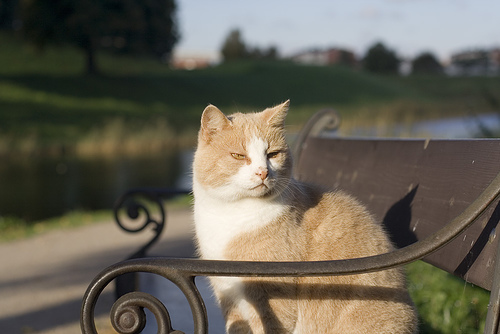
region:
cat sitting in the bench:
[167, 99, 415, 321]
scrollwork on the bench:
[100, 261, 197, 331]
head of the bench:
[181, 97, 299, 217]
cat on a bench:
[177, 80, 436, 331]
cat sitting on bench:
[87, 83, 498, 331]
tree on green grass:
[10, 0, 176, 91]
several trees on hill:
[211, 28, 297, 66]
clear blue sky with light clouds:
[310, 8, 355, 46]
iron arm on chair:
[70, 244, 211, 331]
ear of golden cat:
[194, 95, 230, 142]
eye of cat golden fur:
[227, 143, 254, 170]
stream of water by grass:
[405, 100, 488, 137]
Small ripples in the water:
[23, 179, 38, 206]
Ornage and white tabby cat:
[165, 95, 375, 322]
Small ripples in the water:
[430, 113, 465, 144]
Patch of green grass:
[429, 284, 454, 308]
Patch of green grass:
[439, 308, 493, 330]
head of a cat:
[185, 90, 322, 204]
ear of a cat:
[193, 96, 231, 139]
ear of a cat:
[262, 92, 309, 130]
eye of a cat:
[225, 142, 256, 168]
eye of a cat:
[260, 142, 302, 164]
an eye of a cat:
[220, 145, 251, 167]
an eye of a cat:
[270, 145, 302, 156]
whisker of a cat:
[209, 162, 250, 199]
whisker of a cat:
[270, 158, 313, 195]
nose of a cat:
[253, 159, 278, 179]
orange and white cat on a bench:
[190, 96, 413, 331]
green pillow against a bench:
[393, 247, 483, 327]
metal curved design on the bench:
[77, 164, 494, 330]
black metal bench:
[82, 112, 497, 330]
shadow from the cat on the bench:
[379, 178, 423, 253]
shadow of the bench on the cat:
[216, 280, 415, 332]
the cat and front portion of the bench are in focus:
[85, 96, 496, 331]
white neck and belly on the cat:
[189, 163, 294, 258]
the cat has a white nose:
[245, 134, 267, 179]